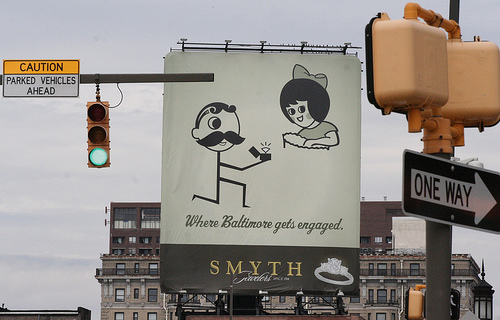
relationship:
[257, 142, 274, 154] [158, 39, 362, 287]
ring on billboard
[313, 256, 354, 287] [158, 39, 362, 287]
ring on billboard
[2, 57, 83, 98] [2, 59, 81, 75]
sign signifies caution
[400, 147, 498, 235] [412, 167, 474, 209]
sign says one way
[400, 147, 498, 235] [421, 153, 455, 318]
sign on pole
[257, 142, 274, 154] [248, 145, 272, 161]
ring in a box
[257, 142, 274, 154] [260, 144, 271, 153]
ring has a diamond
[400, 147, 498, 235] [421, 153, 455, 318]
sign on a pole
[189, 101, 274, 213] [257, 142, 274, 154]
man holding ring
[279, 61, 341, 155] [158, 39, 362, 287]
girl on billboard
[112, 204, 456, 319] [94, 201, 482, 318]
windows are in building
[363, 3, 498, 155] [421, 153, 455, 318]
object on pole